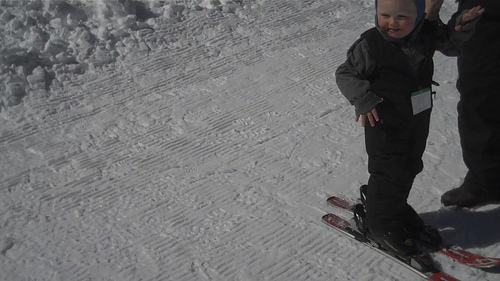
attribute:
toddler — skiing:
[334, 0, 485, 254]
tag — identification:
[412, 89, 432, 119]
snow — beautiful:
[3, 5, 355, 249]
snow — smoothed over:
[108, 109, 258, 276]